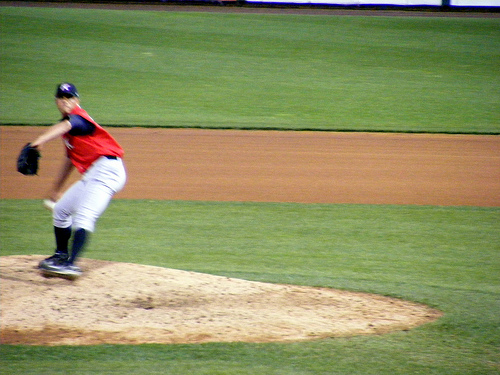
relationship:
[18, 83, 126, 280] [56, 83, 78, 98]
man wearing hat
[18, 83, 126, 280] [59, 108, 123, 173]
man wearing shirt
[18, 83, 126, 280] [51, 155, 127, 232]
man wearing pants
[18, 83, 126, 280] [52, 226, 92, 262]
man wearing socks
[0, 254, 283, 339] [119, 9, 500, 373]
mound in field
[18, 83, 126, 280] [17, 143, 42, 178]
man wearing glove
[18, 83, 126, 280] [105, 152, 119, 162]
man wearing belt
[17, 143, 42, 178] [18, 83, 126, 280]
glove worn by man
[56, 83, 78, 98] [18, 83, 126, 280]
hat atop man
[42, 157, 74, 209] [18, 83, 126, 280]
arm part of man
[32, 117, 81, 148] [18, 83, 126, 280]
arm part of man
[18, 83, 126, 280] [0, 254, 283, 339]
man atop mound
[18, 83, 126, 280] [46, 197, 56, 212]
man holding ball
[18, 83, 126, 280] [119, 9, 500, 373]
man on field